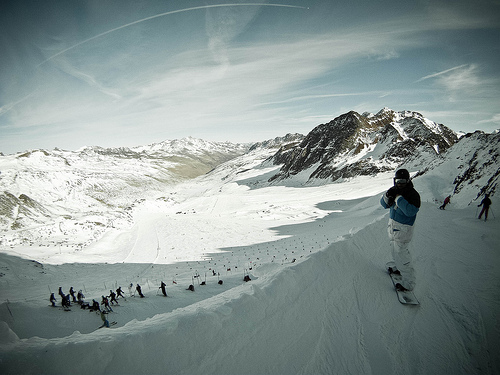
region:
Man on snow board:
[370, 159, 435, 326]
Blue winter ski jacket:
[374, 156, 429, 233]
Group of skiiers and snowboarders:
[31, 260, 279, 337]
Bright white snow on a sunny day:
[137, 198, 174, 243]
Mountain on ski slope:
[264, 104, 498, 171]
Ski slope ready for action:
[16, 109, 495, 368]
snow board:
[378, 255, 427, 317]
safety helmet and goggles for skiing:
[390, 165, 415, 193]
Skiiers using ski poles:
[435, 189, 498, 229]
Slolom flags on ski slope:
[157, 219, 361, 298]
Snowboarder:
[381, 165, 430, 307]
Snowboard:
[386, 259, 418, 307]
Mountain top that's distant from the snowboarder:
[211, 109, 464, 189]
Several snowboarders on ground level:
[49, 251, 301, 327]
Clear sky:
[0, 25, 497, 151]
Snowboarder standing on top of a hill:
[380, 165, 429, 310]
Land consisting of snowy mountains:
[1, 109, 496, 371]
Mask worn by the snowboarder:
[393, 165, 413, 190]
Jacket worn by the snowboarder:
[379, 185, 419, 227]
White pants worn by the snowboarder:
[387, 221, 416, 292]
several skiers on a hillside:
[38, 268, 179, 343]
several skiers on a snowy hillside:
[25, 273, 192, 356]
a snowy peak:
[276, 98, 481, 163]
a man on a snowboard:
[369, 158, 446, 320]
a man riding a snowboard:
[378, 163, 425, 312]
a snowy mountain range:
[1, 113, 366, 189]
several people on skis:
[39, 271, 171, 341]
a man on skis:
[476, 188, 498, 228]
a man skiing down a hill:
[472, 187, 497, 232]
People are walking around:
[27, 272, 262, 332]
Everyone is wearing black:
[22, 273, 202, 336]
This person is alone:
[368, 166, 438, 316]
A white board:
[380, 253, 427, 330]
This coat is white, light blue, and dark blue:
[374, 180, 435, 231]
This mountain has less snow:
[233, 101, 455, 171]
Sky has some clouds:
[42, 18, 279, 122]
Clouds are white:
[41, 22, 275, 123]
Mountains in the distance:
[0, 132, 281, 236]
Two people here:
[438, 185, 499, 230]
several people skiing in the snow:
[24, 239, 275, 339]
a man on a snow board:
[333, 139, 443, 333]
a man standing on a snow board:
[356, 159, 440, 331]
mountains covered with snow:
[89, 112, 454, 209]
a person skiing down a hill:
[425, 185, 462, 227]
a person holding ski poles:
[468, 185, 493, 232]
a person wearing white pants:
[388, 156, 416, 296]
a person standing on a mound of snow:
[377, 164, 429, 332]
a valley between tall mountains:
[38, 166, 310, 293]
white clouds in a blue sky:
[100, 41, 367, 116]